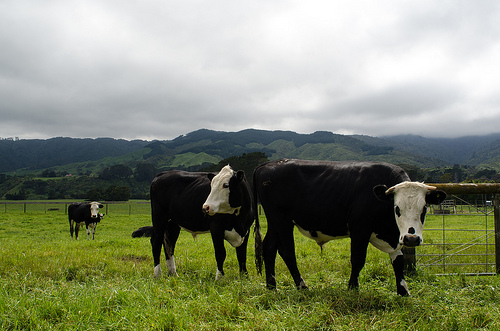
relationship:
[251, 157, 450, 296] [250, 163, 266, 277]
cow has tail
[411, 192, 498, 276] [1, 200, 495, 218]
gate for fence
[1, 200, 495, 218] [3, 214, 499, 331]
fence in grass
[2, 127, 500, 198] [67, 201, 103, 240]
mountainside behind cow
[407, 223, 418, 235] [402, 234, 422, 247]
spot above nose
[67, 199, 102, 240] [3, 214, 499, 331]
cow in grass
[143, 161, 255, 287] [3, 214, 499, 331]
cow in grass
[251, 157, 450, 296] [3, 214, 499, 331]
cow in grass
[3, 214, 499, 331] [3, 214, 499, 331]
grass in grass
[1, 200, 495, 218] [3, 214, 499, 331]
fence around grass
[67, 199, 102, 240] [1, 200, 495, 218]
cow next to fence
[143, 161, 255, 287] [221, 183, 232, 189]
cow has eye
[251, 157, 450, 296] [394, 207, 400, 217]
cow has eye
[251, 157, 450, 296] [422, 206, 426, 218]
cow has eye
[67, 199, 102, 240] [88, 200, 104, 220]
cow has head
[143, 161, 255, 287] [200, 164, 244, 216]
cow has head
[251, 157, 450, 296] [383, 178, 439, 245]
cow has head